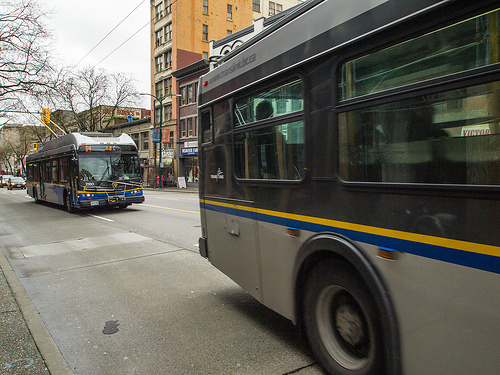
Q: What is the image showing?
A: It is showing a road.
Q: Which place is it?
A: It is a road.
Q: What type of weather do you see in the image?
A: It is cloudy.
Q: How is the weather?
A: It is cloudy.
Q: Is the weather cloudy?
A: Yes, it is cloudy.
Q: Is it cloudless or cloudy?
A: It is cloudy.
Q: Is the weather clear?
A: No, it is cloudy.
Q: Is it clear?
A: No, it is cloudy.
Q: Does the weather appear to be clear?
A: No, it is cloudy.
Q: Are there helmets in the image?
A: No, there are no helmets.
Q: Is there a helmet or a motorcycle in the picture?
A: No, there are no helmets or motorcycles.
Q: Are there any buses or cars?
A: Yes, there is a bus.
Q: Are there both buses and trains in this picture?
A: No, there is a bus but no trains.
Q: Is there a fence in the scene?
A: No, there are no fences.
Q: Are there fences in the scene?
A: No, there are no fences.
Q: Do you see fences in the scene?
A: No, there are no fences.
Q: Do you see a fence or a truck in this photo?
A: No, there are no fences or trucks.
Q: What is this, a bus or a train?
A: This is a bus.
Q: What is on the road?
A: The bus is on the road.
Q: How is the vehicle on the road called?
A: The vehicle is a bus.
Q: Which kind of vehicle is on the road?
A: The vehicle is a bus.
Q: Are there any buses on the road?
A: Yes, there is a bus on the road.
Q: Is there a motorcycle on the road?
A: No, there is a bus on the road.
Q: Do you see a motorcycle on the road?
A: No, there is a bus on the road.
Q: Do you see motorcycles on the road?
A: No, there is a bus on the road.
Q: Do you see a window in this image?
A: Yes, there is a window.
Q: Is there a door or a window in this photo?
A: Yes, there is a window.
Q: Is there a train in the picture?
A: No, there are no trains.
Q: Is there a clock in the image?
A: No, there are no clocks.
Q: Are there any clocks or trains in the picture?
A: No, there are no clocks or trains.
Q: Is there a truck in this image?
A: No, there are no trucks.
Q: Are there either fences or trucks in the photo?
A: No, there are no trucks or fences.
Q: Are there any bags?
A: No, there are no bags.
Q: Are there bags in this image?
A: No, there are no bags.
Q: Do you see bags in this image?
A: No, there are no bags.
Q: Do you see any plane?
A: No, there are no airplanes.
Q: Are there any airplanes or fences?
A: No, there are no airplanes or fences.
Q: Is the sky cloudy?
A: Yes, the sky is cloudy.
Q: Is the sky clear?
A: No, the sky is cloudy.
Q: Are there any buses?
A: Yes, there is a bus.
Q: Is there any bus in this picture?
A: Yes, there is a bus.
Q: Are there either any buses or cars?
A: Yes, there is a bus.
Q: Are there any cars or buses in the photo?
A: Yes, there is a bus.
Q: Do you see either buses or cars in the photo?
A: Yes, there is a bus.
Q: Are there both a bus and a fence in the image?
A: No, there is a bus but no fences.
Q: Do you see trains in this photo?
A: No, there are no trains.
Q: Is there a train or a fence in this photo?
A: No, there are no trains or fences.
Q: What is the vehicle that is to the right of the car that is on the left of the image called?
A: The vehicle is a bus.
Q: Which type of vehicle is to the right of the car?
A: The vehicle is a bus.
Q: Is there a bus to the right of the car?
A: Yes, there is a bus to the right of the car.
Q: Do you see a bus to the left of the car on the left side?
A: No, the bus is to the right of the car.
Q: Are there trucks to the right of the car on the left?
A: No, there is a bus to the right of the car.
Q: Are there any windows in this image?
A: Yes, there is a window.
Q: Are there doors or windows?
A: Yes, there is a window.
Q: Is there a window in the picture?
A: Yes, there is a window.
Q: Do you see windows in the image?
A: Yes, there is a window.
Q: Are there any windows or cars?
A: Yes, there is a window.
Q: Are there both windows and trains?
A: No, there is a window but no trains.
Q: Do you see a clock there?
A: No, there are no clocks.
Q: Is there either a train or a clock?
A: No, there are no clocks or trains.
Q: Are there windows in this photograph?
A: Yes, there is a window.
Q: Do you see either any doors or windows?
A: Yes, there is a window.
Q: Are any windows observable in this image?
A: Yes, there is a window.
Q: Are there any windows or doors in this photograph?
A: Yes, there is a window.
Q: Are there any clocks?
A: No, there are no clocks.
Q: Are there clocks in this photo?
A: No, there are no clocks.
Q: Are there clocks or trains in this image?
A: No, there are no clocks or trains.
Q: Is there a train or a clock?
A: No, there are no clocks or trains.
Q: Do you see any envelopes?
A: No, there are no envelopes.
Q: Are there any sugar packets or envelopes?
A: No, there are no envelopes or sugar packets.